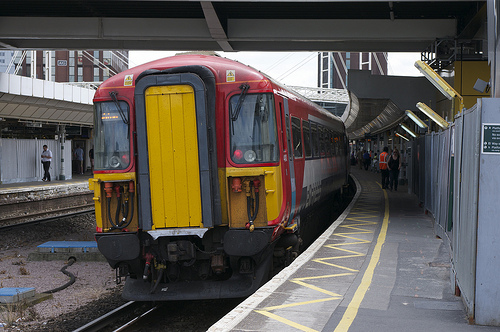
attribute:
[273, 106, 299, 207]
doors — grey 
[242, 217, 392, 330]
lines — yellow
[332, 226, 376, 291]
line — yellow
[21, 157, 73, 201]
pants — dark 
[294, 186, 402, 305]
line — yellow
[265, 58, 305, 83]
sky — grey , white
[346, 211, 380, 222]
line — yellow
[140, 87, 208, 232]
door — Yellow 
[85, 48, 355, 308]
train — red , white, yellow 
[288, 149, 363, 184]
trim — white 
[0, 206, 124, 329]
ground — black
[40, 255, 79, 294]
hose — thick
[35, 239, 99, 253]
box — blue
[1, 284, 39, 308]
box — blue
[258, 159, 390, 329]
lines — yellow 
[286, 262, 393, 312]
yellow/painted line — yellow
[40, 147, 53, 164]
shirt — white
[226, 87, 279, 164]
window — rectangular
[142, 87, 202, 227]
door — yellow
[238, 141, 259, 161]
light — red 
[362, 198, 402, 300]
line — yellow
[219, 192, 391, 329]
line — yellow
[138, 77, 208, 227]
door — blue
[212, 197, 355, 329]
white line — solid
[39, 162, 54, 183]
pants — black 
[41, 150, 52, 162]
shirt — white 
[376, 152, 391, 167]
vest — orange 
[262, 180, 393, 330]
line — yellow 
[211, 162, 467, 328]
platform — gray, pavement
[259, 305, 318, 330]
line — yellow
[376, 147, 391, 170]
vest — orange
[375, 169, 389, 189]
pants — dark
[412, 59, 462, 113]
light — yellow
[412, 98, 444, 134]
light — yellow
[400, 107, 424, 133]
light — yellow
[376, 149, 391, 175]
top — orange